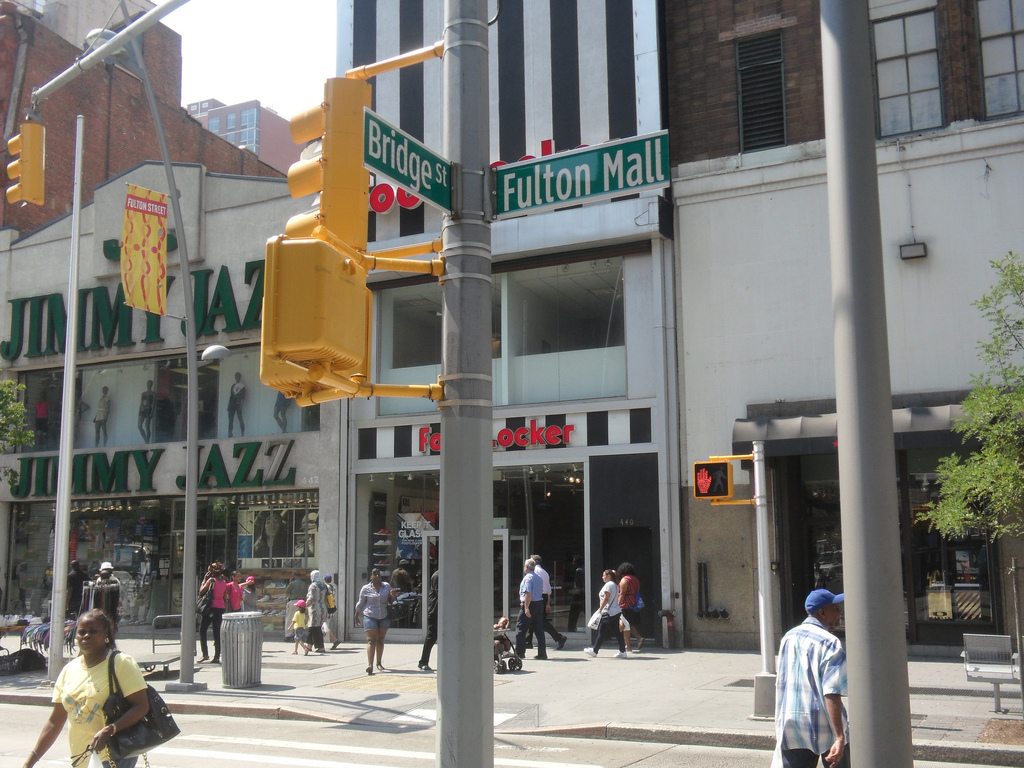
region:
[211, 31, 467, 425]
yellow holder for traffic lights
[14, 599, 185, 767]
woman in yellow shirt with black purse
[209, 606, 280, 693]
a grey metal garbage can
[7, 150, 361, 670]
a white building with Jimmy Jazz name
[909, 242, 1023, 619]
trees with green leaves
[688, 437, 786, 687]
a traffic sign with "don't walk" symbol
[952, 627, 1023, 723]
a wooden park bench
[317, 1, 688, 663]
a store that has black and white stripes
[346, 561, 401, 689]
person wearing blue shorts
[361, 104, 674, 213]
green signs with street names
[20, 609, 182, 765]
woman with yellow shirt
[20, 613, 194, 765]
woman wearing yellow shirt holding black bag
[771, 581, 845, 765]
man in plaid shirt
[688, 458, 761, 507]
do not walk signal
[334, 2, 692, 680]
people in front of Footlocker storefront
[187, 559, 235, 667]
woman wearing pink shirt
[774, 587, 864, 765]
man in plaid shirt with blue cap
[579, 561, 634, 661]
woman holding bags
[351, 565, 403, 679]
woman wearing denim shorts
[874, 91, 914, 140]
pane on window in front of building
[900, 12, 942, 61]
pane on window in front of building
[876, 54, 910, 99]
pane on window in front of building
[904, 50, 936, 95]
pane on window in front of building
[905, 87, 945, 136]
pane on window in front of building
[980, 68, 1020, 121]
pane on window in front of building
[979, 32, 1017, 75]
pane on window in front of building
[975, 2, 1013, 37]
pane on window in front of building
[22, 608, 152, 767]
Black woman in a yellow t-shirt.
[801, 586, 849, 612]
Blue hat on a walking man.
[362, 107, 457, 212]
Green and white Bridge St. sign.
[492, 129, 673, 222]
White and green Fulton Mall sign.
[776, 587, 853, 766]
Black man in a white and blue shirt and blue cap.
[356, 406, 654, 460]
Black and white striped Footlocker sign with red letters.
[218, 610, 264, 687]
Silver trash can on the sidewalk.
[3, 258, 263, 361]
Larger green JIMMY JAZZ sign above the smaller one.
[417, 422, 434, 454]
Red letter F in Footlocker.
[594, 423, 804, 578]
hand on the object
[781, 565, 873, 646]
head of the man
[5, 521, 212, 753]
woman with a yellow shirt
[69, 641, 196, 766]
object around lady's shoulder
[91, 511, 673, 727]
people walking on sidewalk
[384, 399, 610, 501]
words above the ground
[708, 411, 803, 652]
pole next to street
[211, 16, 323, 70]
sky above the land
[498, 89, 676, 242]
green and white street sign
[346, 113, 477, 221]
green and white street sign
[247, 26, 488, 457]
yellow painted traffic light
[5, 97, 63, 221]
yellow painted traffic light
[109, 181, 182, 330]
yellow and red banner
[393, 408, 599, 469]
red footlocker sign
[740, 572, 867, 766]
man wearing blue baseball hat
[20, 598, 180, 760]
woman wearing yellow shirt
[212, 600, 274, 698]
silver metal trashcan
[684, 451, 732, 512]
orange walking sign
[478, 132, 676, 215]
a green and white street sign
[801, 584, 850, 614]
a blue baseball cap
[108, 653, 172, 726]
a large black purse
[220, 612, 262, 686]
a tall gray trashcan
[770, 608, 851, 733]
a man's striped short sleeve blue and white shirt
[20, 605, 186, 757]
person crossing the street